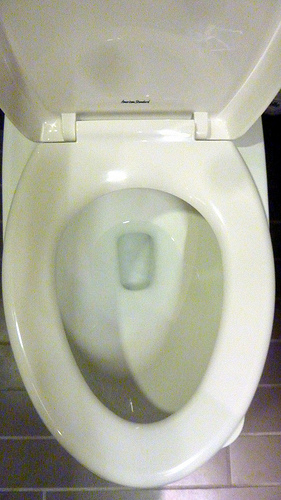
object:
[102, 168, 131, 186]
light glare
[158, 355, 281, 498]
glare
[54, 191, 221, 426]
toilet bowl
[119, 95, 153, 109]
brand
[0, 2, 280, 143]
seat lid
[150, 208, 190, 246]
reflection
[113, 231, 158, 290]
water drain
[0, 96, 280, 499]
tiled floor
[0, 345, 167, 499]
dark tiles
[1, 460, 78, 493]
white grout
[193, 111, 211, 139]
seat hinge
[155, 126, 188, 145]
light glare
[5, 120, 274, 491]
seat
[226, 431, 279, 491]
rectangle tiles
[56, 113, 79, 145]
toilet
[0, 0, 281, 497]
bathroom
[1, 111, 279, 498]
floor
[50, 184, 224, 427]
water